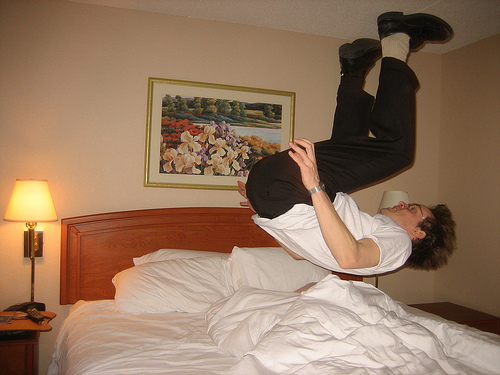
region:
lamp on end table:
[4, 180, 60, 317]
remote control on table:
[28, 307, 44, 324]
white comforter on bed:
[141, 281, 498, 373]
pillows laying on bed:
[112, 245, 318, 307]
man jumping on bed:
[246, 12, 455, 274]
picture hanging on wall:
[144, 75, 296, 192]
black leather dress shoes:
[338, 12, 453, 65]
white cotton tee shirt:
[248, 193, 414, 274]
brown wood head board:
[58, 208, 273, 303]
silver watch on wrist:
[308, 183, 324, 195]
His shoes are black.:
[328, 10, 464, 63]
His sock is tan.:
[358, 24, 423, 66]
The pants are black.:
[235, 63, 431, 204]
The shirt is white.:
[265, 190, 407, 279]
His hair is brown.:
[413, 198, 460, 288]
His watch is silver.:
[304, 182, 324, 197]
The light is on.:
[1, 173, 66, 228]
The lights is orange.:
[4, 180, 61, 225]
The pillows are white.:
[120, 251, 314, 310]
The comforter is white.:
[58, 294, 487, 373]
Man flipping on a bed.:
[244, 16, 493, 301]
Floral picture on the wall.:
[135, 67, 302, 199]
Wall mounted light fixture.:
[0, 164, 77, 324]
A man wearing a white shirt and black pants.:
[220, 11, 480, 298]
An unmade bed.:
[41, 174, 498, 369]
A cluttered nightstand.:
[0, 267, 67, 372]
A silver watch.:
[267, 137, 348, 219]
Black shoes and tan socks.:
[306, 8, 477, 113]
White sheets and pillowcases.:
[60, 263, 478, 373]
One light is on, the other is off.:
[6, 146, 456, 276]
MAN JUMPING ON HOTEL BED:
[265, 30, 432, 300]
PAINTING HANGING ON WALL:
[97, 75, 312, 200]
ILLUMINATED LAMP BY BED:
[2, 169, 96, 358]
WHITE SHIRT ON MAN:
[270, 151, 413, 266]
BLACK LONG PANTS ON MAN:
[242, 53, 409, 174]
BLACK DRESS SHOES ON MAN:
[360, 5, 459, 77]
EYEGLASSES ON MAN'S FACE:
[400, 188, 433, 220]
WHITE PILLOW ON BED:
[117, 259, 205, 323]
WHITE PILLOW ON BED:
[244, 228, 321, 298]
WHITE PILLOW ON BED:
[157, 227, 232, 267]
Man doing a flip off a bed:
[47, 10, 499, 373]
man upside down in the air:
[237, 8, 457, 275]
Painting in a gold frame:
[143, 75, 295, 191]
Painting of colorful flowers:
[157, 85, 283, 176]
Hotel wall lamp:
[1, 176, 58, 301]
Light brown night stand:
[0, 308, 55, 374]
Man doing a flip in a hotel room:
[0, 0, 498, 372]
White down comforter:
[203, 274, 498, 374]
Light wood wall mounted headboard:
[56, 205, 365, 305]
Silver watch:
[307, 180, 327, 198]